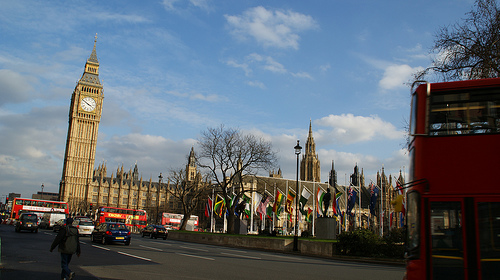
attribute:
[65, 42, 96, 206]
clock — big, huge, building, brown, big ben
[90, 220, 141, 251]
car — blue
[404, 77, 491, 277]
bus — big, red, london, two stories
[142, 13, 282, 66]
sky — cloudy, blue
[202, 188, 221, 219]
flag — waving, flying, on pole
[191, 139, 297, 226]
tree — bare, green